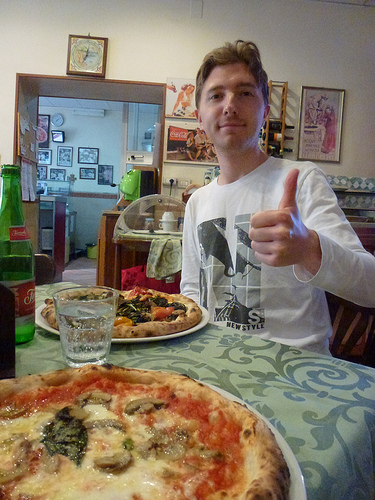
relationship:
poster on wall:
[156, 117, 222, 172] [1, 0, 366, 220]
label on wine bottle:
[272, 130, 282, 140] [263, 131, 295, 142]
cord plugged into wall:
[169, 178, 172, 197] [4, 2, 374, 188]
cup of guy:
[50, 281, 123, 368] [180, 38, 375, 354]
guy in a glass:
[180, 38, 375, 354] [46, 281, 132, 373]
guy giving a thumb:
[180, 38, 375, 354] [276, 163, 301, 212]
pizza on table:
[0, 351, 293, 498] [7, 273, 371, 497]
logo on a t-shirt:
[196, 216, 265, 326] [179, 156, 374, 366]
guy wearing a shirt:
[180, 38, 375, 354] [179, 155, 373, 356]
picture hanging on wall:
[66, 32, 108, 79] [0, 0, 373, 255]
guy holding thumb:
[180, 38, 375, 354] [277, 167, 298, 207]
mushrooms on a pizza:
[91, 392, 188, 471] [119, 284, 198, 334]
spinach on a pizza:
[36, 402, 88, 468] [119, 284, 198, 334]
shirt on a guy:
[179, 155, 373, 356] [136, 2, 355, 278]